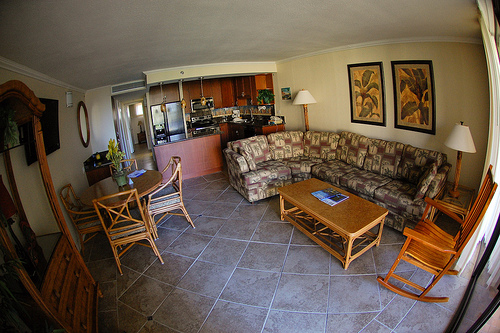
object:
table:
[274, 177, 389, 270]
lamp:
[442, 119, 477, 197]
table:
[430, 183, 480, 228]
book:
[309, 187, 351, 205]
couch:
[223, 129, 452, 234]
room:
[4, 31, 499, 332]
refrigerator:
[151, 99, 187, 143]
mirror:
[78, 98, 91, 146]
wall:
[0, 89, 122, 268]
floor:
[188, 246, 275, 311]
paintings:
[346, 60, 437, 136]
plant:
[102, 139, 128, 187]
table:
[64, 169, 164, 251]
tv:
[11, 99, 58, 167]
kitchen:
[149, 74, 272, 147]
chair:
[91, 187, 168, 275]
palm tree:
[348, 60, 390, 127]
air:
[0, 0, 499, 116]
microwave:
[189, 96, 214, 111]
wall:
[281, 21, 481, 160]